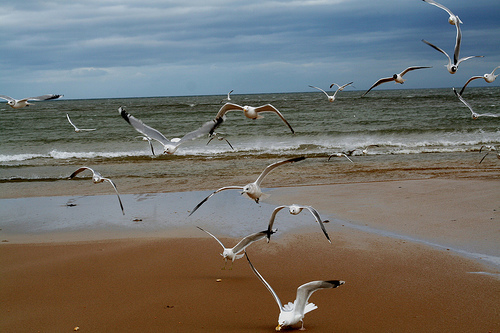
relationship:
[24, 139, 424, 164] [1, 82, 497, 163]
waves on ocean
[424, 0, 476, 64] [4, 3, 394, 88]
bird in sky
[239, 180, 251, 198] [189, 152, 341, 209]
head of a bird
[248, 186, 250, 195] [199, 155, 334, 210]
eye of a bird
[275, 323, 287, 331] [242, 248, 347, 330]
foot of a bird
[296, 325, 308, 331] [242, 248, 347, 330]
foot of a bird